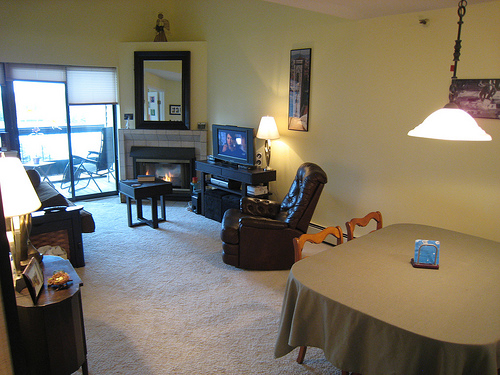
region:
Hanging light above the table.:
[410, 1, 492, 146]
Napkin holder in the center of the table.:
[411, 229, 446, 271]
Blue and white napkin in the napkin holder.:
[410, 237, 445, 266]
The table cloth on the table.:
[277, 208, 498, 371]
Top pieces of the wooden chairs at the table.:
[286, 218, 382, 246]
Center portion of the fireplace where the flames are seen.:
[128, 146, 193, 189]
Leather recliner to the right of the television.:
[213, 163, 326, 270]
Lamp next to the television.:
[258, 107, 278, 170]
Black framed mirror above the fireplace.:
[131, 53, 198, 129]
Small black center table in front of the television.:
[111, 173, 175, 230]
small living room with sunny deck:
[49, 72, 399, 318]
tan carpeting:
[137, 249, 239, 341]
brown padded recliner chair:
[219, 147, 324, 289]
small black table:
[109, 160, 177, 240]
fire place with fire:
[112, 123, 204, 201]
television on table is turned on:
[200, 119, 270, 186]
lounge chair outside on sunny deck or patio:
[55, 97, 115, 199]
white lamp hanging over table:
[409, 9, 481, 165]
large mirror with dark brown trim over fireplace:
[122, 40, 187, 129]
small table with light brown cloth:
[263, 197, 486, 364]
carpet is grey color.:
[107, 268, 198, 370]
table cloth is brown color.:
[315, 266, 415, 329]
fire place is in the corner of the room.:
[137, 152, 204, 188]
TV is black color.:
[206, 120, 266, 180]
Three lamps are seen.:
[0, 96, 495, 217]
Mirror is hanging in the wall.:
[130, 52, 215, 127]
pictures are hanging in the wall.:
[270, 55, 492, 151]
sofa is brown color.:
[211, 190, 291, 262]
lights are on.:
[0, 127, 495, 217]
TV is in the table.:
[201, 149, 265, 188]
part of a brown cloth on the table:
[378, 282, 425, 316]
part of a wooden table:
[299, 225, 334, 247]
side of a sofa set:
[229, 224, 270, 267]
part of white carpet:
[183, 306, 235, 353]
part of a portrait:
[287, 79, 311, 127]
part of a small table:
[130, 176, 155, 196]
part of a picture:
[24, 276, 50, 294]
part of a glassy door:
[73, 113, 95, 176]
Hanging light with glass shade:
[402, 0, 496, 158]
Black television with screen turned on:
[199, 109, 269, 171]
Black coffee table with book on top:
[107, 162, 180, 242]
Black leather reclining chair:
[202, 147, 347, 281]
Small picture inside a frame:
[16, 252, 50, 308]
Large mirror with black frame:
[122, 38, 209, 141]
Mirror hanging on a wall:
[275, 39, 322, 148]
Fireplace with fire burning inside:
[119, 143, 204, 199]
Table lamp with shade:
[252, 108, 287, 172]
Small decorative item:
[141, 8, 180, 43]